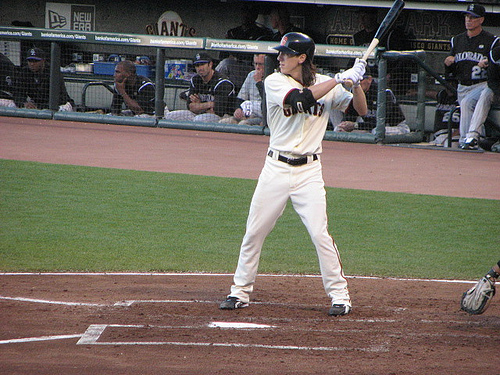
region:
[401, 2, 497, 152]
Player steps up dug-out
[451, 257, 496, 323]
Catcher's mitt right dirt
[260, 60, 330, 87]
Baseball batter long brown hair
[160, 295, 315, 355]
Home plate white smudge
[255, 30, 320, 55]
Blue safety helmet head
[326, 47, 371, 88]
White gloves better grip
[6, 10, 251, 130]
Giants team wait dugout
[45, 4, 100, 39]
New Era advertisement sign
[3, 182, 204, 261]
Baseball field green turf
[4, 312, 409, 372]
Home plate dirt white lines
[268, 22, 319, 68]
hard dark blue batter helmet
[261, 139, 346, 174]
black belt in uniform pants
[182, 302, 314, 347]
white home base with dirt on it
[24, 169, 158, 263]
green grass in ball field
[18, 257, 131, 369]
white lines painted on red dirt of ball field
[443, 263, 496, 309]
catchers glove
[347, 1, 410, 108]
two tone wooden caseball bat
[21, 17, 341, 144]
metal seperting field from dug out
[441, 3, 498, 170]
man in black and white baseball uniform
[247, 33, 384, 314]
man in white baseball uniform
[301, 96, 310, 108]
part of a elbow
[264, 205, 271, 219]
part of a trouser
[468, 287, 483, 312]
part of a glove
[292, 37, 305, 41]
part of a helmet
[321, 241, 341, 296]
right leg of a man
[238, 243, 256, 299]
left leg of a man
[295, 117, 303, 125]
part of a jersey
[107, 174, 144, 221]
part of a grass lawn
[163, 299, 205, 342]
part of a field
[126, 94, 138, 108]
part of a fence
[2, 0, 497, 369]
a baseball game in progress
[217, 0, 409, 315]
a baseball player ready to hit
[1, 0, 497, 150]
people in the dugout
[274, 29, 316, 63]
a baseball helmet on head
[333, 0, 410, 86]
man holding baseball bat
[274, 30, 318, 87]
baseball player with long hair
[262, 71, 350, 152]
a white baseball jersey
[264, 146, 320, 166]
a baseball player's black belt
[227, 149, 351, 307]
a baseball player's white pants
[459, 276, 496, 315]
a baseball player's catcher's mitt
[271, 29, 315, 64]
black and red baseball helmet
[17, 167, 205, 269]
green grass on baseball field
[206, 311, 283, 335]
white plate on batter's mound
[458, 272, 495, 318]
black catcher's glove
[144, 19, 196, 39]
red Giants logo on wall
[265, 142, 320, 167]
black leather belt around waist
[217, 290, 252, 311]
black baseball cleat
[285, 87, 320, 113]
elbow brace on right elbow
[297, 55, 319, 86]
long hair flowing out from under helmet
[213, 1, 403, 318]
baseball player up at bat